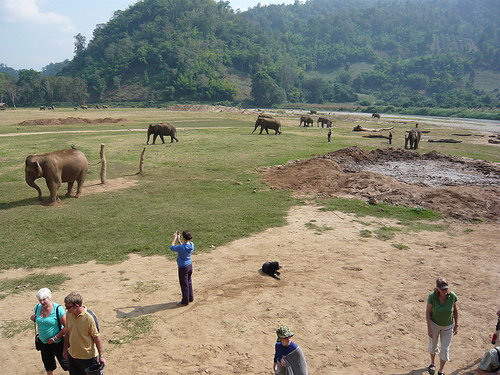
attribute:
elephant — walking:
[145, 123, 181, 143]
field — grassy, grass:
[0, 109, 498, 375]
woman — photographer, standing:
[171, 230, 195, 307]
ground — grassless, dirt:
[67, 263, 499, 375]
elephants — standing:
[253, 114, 334, 135]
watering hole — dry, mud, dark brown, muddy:
[283, 146, 499, 214]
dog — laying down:
[260, 261, 284, 280]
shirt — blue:
[171, 242, 194, 267]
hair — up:
[181, 230, 192, 241]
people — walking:
[31, 287, 107, 374]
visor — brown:
[435, 278, 449, 290]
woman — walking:
[29, 287, 67, 374]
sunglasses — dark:
[65, 305, 77, 309]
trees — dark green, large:
[0, 1, 499, 109]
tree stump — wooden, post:
[99, 142, 108, 183]